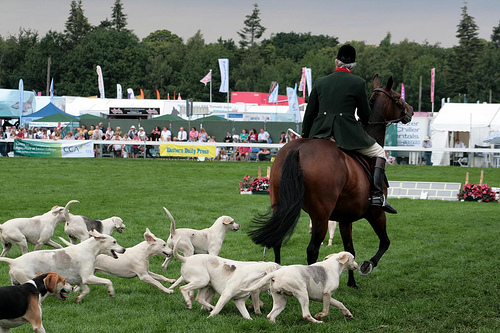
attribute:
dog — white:
[95, 233, 177, 310]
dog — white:
[239, 249, 360, 324]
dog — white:
[157, 203, 240, 271]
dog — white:
[6, 200, 71, 258]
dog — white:
[97, 227, 176, 289]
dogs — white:
[88, 198, 360, 329]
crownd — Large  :
[75, 116, 275, 147]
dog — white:
[177, 254, 277, 317]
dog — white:
[164, 214, 240, 270]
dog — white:
[9, 232, 125, 303]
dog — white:
[245, 237, 377, 319]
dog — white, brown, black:
[4, 200, 373, 325]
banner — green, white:
[12, 138, 96, 158]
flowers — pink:
[239, 172, 261, 194]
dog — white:
[64, 194, 127, 246]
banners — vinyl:
[12, 137, 92, 158]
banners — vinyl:
[159, 144, 214, 156]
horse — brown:
[251, 71, 419, 293]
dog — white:
[236, 220, 394, 318]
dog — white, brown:
[0, 270, 72, 330]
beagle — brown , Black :
[3, 269, 72, 330]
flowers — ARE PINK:
[455, 182, 499, 205]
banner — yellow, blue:
[153, 128, 236, 167]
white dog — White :
[74, 209, 127, 235]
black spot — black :
[85, 216, 107, 230]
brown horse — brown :
[260, 126, 400, 251]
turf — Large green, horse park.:
[5, 157, 499, 329]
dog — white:
[165, 205, 317, 305]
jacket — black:
[299, 69, 379, 154]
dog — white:
[3, 236, 118, 306]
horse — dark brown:
[227, 69, 445, 310]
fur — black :
[114, 240, 152, 271]